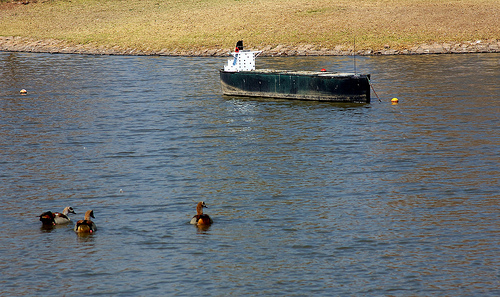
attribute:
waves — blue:
[246, 152, 451, 270]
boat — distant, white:
[212, 30, 381, 110]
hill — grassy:
[2, 4, 498, 53]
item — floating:
[13, 83, 29, 95]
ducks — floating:
[33, 197, 216, 240]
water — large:
[10, 54, 490, 295]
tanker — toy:
[213, 34, 378, 112]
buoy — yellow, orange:
[384, 90, 402, 110]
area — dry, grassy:
[4, 4, 498, 51]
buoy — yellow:
[15, 83, 33, 95]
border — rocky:
[12, 37, 499, 58]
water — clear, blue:
[266, 117, 482, 260]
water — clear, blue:
[104, 112, 185, 186]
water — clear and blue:
[194, 115, 455, 242]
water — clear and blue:
[263, 123, 377, 250]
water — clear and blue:
[313, 130, 443, 234]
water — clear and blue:
[268, 171, 366, 264]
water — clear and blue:
[268, 186, 381, 292]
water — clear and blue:
[286, 145, 446, 239]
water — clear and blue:
[293, 158, 472, 265]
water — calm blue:
[254, 144, 433, 277]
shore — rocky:
[29, 24, 175, 105]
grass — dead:
[85, 3, 209, 56]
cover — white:
[219, 30, 276, 95]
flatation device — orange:
[373, 73, 422, 119]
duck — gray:
[37, 180, 98, 242]